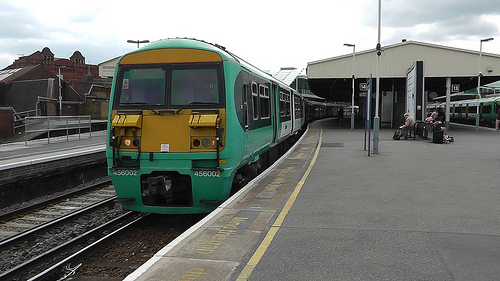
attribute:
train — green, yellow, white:
[102, 29, 358, 226]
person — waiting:
[391, 111, 417, 142]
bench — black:
[406, 118, 438, 144]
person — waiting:
[426, 108, 453, 143]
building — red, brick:
[3, 44, 109, 105]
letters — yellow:
[167, 133, 316, 280]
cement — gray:
[134, 122, 500, 280]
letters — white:
[109, 164, 224, 181]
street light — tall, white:
[337, 39, 361, 140]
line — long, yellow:
[230, 122, 322, 279]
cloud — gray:
[356, 2, 498, 44]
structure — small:
[267, 62, 308, 89]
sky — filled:
[2, 0, 499, 72]